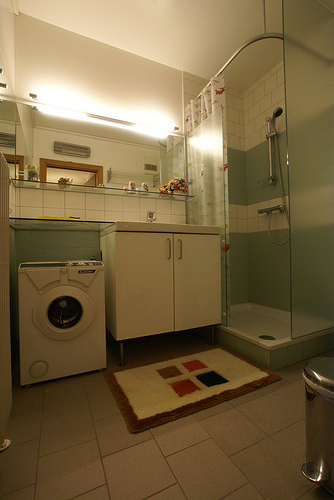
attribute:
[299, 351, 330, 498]
trash can — silver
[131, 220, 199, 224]
sink — white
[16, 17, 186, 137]
wall — white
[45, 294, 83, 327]
window — round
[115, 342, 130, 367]
leg — silver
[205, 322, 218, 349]
leg — silver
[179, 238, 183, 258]
handle — silver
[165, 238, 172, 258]
handle — silver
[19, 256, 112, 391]
washing machine — frong loading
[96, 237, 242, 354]
cupboards — white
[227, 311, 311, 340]
floor — white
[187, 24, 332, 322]
wall — tiled, green, white